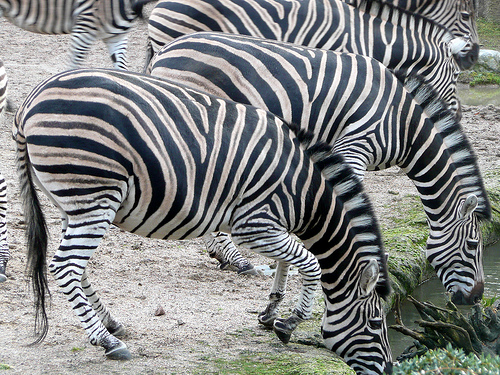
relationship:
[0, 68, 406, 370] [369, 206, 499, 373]
zebra drinking water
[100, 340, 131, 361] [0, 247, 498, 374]
hoof on top of ground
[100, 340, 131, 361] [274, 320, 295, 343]
hoof next to hoof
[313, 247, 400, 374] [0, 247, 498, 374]
head next to ground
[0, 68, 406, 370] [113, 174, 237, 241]
zebra has belly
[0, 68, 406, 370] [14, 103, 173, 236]
zebra has stripe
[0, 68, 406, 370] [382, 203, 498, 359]
zebra drinking water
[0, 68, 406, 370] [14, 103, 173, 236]
zebra have stripe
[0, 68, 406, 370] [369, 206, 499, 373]
zebra next to water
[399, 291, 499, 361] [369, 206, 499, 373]
roots are inside of water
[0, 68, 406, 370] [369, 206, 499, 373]
zebra near water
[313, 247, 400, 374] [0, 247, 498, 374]
head near ground